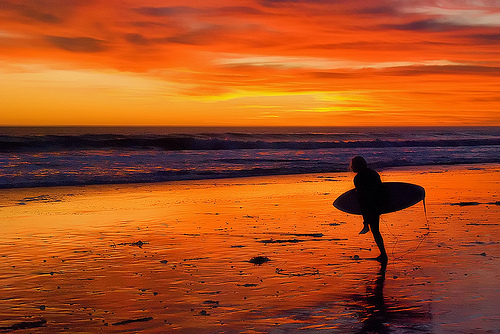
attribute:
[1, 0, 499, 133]
sky — orange, red, yellow, part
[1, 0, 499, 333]
picture — evening, sunset, beautiful, outdoors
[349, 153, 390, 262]
person — walking, surfing, surfer, tilted, looking, standing, pretty, woman, black, silhouette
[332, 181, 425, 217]
surfboard — dripping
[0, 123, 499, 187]
water — ocean, red, purple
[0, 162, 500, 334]
sand — reflective, footprinted, beautiful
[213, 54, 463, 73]
cloud — whispy, part, some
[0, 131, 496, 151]
wave — breaking, part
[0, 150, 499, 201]
coastline — beautiful